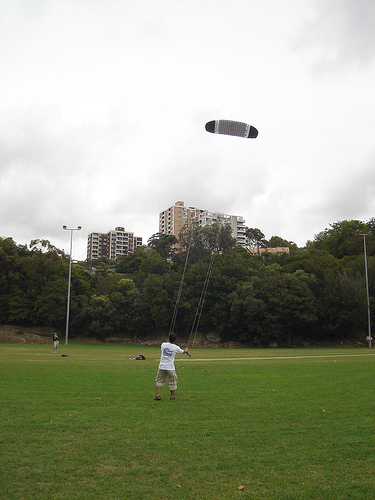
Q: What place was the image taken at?
A: It was taken at the park.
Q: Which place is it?
A: It is a park.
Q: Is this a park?
A: Yes, it is a park.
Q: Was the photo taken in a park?
A: Yes, it was taken in a park.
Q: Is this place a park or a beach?
A: It is a park.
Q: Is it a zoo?
A: No, it is a park.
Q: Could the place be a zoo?
A: No, it is a park.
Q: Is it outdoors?
A: Yes, it is outdoors.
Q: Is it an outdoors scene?
A: Yes, it is outdoors.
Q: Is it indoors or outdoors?
A: It is outdoors.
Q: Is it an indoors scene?
A: No, it is outdoors.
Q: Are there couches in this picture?
A: No, there are no couches.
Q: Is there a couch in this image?
A: No, there are no couches.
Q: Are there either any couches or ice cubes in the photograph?
A: No, there are no couches or ice cubes.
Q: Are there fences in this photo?
A: No, there are no fences.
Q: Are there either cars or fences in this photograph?
A: No, there are no fences or cars.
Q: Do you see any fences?
A: No, there are no fences.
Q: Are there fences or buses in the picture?
A: No, there are no fences or buses.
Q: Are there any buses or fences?
A: No, there are no fences or buses.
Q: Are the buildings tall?
A: Yes, the buildings are tall.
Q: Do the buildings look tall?
A: Yes, the buildings are tall.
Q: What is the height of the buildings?
A: The buildings are tall.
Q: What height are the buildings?
A: The buildings are tall.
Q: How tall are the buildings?
A: The buildings are tall.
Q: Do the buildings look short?
A: No, the buildings are tall.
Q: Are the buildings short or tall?
A: The buildings are tall.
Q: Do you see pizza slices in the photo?
A: No, there are no pizza slices.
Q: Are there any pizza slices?
A: No, there are no pizza slices.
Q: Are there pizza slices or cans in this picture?
A: No, there are no pizza slices or cans.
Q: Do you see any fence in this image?
A: No, there are no fences.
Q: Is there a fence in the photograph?
A: No, there are no fences.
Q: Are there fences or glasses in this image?
A: No, there are no fences or glasses.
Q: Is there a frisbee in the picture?
A: No, there are no frisbees.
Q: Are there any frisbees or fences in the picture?
A: No, there are no frisbees or fences.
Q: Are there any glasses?
A: No, there are no glasses.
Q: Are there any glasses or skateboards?
A: No, there are no glasses or skateboards.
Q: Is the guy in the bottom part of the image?
A: Yes, the guy is in the bottom of the image.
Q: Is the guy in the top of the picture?
A: No, the guy is in the bottom of the image.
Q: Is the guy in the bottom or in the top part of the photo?
A: The guy is in the bottom of the image.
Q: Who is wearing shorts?
A: The guy is wearing shorts.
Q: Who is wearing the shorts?
A: The guy is wearing shorts.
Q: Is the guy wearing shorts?
A: Yes, the guy is wearing shorts.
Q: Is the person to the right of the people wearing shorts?
A: Yes, the guy is wearing shorts.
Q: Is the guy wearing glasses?
A: No, the guy is wearing shorts.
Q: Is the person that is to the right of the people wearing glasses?
A: No, the guy is wearing shorts.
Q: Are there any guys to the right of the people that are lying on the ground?
A: Yes, there is a guy to the right of the people.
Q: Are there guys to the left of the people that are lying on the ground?
A: No, the guy is to the right of the people.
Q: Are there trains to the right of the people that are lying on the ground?
A: No, there is a guy to the right of the people.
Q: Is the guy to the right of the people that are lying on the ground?
A: Yes, the guy is to the right of the people.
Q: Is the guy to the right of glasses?
A: No, the guy is to the right of the people.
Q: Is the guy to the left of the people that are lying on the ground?
A: No, the guy is to the right of the people.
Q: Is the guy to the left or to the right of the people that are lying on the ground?
A: The guy is to the right of the people.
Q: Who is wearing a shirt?
A: The guy is wearing a shirt.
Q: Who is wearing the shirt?
A: The guy is wearing a shirt.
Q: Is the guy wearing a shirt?
A: Yes, the guy is wearing a shirt.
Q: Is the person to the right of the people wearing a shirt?
A: Yes, the guy is wearing a shirt.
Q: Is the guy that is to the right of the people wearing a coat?
A: No, the guy is wearing a shirt.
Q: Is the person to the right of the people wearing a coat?
A: No, the guy is wearing a shirt.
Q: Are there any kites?
A: Yes, there is a kite.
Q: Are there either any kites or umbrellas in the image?
A: Yes, there is a kite.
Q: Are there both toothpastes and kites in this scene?
A: No, there is a kite but no toothpastes.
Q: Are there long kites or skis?
A: Yes, there is a long kite.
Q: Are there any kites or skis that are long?
A: Yes, the kite is long.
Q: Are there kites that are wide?
A: Yes, there is a wide kite.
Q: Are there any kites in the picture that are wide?
A: Yes, there is a kite that is wide.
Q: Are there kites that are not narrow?
A: Yes, there is a wide kite.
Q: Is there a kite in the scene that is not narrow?
A: Yes, there is a wide kite.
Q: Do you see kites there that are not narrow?
A: Yes, there is a wide kite.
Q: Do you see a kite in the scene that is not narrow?
A: Yes, there is a wide kite.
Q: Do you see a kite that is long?
A: Yes, there is a long kite.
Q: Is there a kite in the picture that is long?
A: Yes, there is a kite that is long.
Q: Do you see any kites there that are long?
A: Yes, there is a kite that is long.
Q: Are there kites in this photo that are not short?
A: Yes, there is a long kite.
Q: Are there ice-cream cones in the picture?
A: No, there are no ice-cream cones.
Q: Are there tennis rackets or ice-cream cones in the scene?
A: No, there are no ice-cream cones or tennis rackets.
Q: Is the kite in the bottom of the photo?
A: No, the kite is in the top of the image.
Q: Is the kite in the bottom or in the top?
A: The kite is in the top of the image.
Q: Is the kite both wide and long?
A: Yes, the kite is wide and long.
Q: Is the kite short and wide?
A: No, the kite is wide but long.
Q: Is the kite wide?
A: Yes, the kite is wide.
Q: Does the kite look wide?
A: Yes, the kite is wide.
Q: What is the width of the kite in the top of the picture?
A: The kite is wide.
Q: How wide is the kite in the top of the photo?
A: The kite is wide.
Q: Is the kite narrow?
A: No, the kite is wide.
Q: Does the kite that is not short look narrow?
A: No, the kite is wide.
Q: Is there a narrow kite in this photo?
A: No, there is a kite but it is wide.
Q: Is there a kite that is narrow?
A: No, there is a kite but it is wide.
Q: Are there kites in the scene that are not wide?
A: No, there is a kite but it is wide.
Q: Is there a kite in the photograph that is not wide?
A: No, there is a kite but it is wide.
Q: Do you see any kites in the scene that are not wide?
A: No, there is a kite but it is wide.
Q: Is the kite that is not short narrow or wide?
A: The kite is wide.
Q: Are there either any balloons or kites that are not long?
A: No, there is a kite but it is long.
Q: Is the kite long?
A: Yes, the kite is long.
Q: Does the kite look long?
A: Yes, the kite is long.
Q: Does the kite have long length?
A: Yes, the kite is long.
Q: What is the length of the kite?
A: The kite is long.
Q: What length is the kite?
A: The kite is long.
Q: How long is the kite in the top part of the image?
A: The kite is long.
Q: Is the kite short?
A: No, the kite is long.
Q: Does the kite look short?
A: No, the kite is long.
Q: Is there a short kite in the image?
A: No, there is a kite but it is long.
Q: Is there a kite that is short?
A: No, there is a kite but it is long.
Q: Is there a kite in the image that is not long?
A: No, there is a kite but it is long.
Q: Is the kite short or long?
A: The kite is long.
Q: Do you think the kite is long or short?
A: The kite is long.